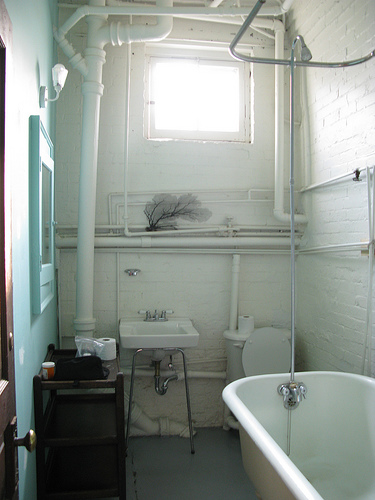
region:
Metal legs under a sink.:
[123, 349, 195, 454]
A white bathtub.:
[218, 370, 373, 498]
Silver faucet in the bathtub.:
[288, 385, 303, 405]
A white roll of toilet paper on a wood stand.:
[96, 338, 117, 360]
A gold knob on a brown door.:
[14, 428, 37, 451]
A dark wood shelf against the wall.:
[32, 343, 126, 499]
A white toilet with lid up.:
[220, 323, 295, 383]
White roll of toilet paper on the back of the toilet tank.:
[236, 314, 254, 333]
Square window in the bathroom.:
[143, 51, 246, 139]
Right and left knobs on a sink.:
[136, 310, 174, 320]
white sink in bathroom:
[115, 307, 190, 344]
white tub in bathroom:
[180, 377, 362, 498]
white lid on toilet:
[234, 318, 295, 388]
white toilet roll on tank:
[228, 310, 258, 331]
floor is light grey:
[150, 444, 203, 497]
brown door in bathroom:
[1, 282, 33, 489]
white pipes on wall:
[254, 88, 369, 256]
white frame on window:
[143, 56, 245, 137]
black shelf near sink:
[35, 348, 144, 493]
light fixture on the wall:
[37, 63, 67, 106]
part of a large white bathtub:
[222, 370, 374, 499]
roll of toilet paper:
[238, 312, 253, 332]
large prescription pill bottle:
[42, 361, 54, 379]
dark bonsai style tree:
[142, 191, 211, 230]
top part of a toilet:
[224, 328, 295, 380]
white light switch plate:
[18, 347, 24, 365]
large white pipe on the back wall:
[55, 235, 300, 248]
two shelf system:
[32, 343, 127, 496]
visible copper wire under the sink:
[154, 359, 159, 374]